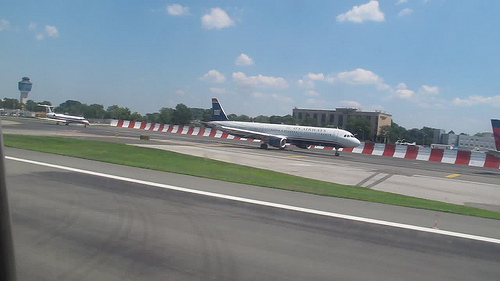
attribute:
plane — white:
[198, 94, 363, 161]